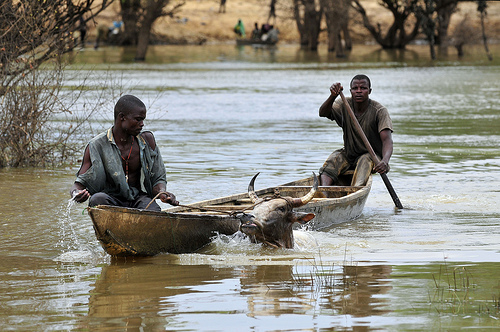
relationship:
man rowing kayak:
[314, 72, 395, 190] [86, 163, 374, 264]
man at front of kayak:
[69, 95, 181, 214] [86, 163, 374, 264]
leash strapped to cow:
[142, 188, 293, 217] [236, 170, 321, 251]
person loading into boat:
[251, 20, 263, 40] [235, 34, 281, 47]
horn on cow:
[244, 168, 263, 207] [236, 170, 321, 251]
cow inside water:
[236, 170, 321, 251] [1, 64, 499, 332]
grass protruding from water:
[421, 257, 498, 326] [1, 64, 499, 332]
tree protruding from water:
[1, 0, 127, 171] [1, 64, 499, 332]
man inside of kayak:
[69, 95, 181, 214] [86, 163, 374, 264]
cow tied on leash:
[236, 170, 321, 251] [142, 188, 293, 217]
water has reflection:
[1, 64, 499, 332] [236, 261, 397, 324]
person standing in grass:
[233, 18, 248, 44] [225, 31, 251, 40]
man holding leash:
[69, 95, 181, 214] [142, 188, 293, 217]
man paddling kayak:
[314, 72, 395, 190] [86, 163, 374, 264]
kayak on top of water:
[86, 163, 374, 264] [1, 64, 499, 332]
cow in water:
[236, 170, 321, 251] [1, 64, 499, 332]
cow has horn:
[236, 170, 321, 251] [244, 168, 263, 207]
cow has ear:
[236, 170, 321, 251] [294, 211, 318, 229]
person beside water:
[233, 18, 248, 44] [1, 64, 499, 332]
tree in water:
[1, 0, 127, 171] [1, 64, 499, 332]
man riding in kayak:
[69, 95, 181, 214] [86, 163, 374, 264]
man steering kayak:
[314, 72, 395, 190] [86, 163, 374, 264]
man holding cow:
[314, 72, 395, 190] [236, 170, 321, 251]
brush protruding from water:
[0, 69, 123, 173] [1, 64, 499, 332]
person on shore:
[233, 18, 248, 44] [0, 11, 500, 59]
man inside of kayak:
[314, 72, 395, 190] [86, 163, 374, 264]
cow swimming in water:
[236, 170, 321, 251] [1, 64, 499, 332]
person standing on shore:
[233, 18, 248, 44] [0, 11, 500, 59]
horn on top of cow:
[244, 168, 263, 207] [236, 170, 321, 251]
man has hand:
[69, 95, 181, 214] [71, 186, 92, 207]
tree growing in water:
[127, 0, 184, 61] [1, 64, 499, 332]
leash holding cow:
[142, 188, 293, 217] [236, 170, 321, 251]